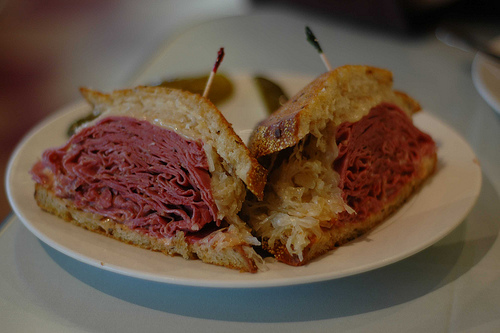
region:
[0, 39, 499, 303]
two halves of a sandwich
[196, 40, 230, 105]
toothpick sticking out of the sandwich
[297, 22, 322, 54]
top of the toothpick is green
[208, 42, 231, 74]
top of the toothpick is red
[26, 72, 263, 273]
meat between the bread slices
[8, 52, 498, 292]
round white plate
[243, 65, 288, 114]
pickle on the plate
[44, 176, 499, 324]
shadow from the plate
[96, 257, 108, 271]
speck on the edge of the plate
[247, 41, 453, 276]
A half sliced burgar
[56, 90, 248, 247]
A half sliced burgar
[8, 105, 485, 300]
A white plate of food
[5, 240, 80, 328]
A white plate surface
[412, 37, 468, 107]
A white plate surface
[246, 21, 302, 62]
A white plate surface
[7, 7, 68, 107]
A blurred photo background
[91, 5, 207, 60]
A blurred photo background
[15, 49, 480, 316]
a bunch of sandwhiches on a plate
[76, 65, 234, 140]
the bread of a sandwhich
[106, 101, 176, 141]
the cheese of a sandwhich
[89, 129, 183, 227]
the beef of a sandwhich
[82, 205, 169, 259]
the bottom bread of a sandwhich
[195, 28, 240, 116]
a tooth pick sticking out of a sandwhich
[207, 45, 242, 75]
a piece of plastic on a toothpick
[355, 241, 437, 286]
a white ceramic plate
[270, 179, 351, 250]
the saurkraut of a sandwhich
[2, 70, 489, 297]
A white round plate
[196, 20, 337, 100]
Two toothpicks on sandwiches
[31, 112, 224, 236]
A lot of ham in a sandwich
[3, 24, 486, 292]
Two sandwiches on a plate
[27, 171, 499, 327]
Plate's shadow on the table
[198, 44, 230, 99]
Red wrapper on a toothpick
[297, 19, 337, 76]
Green wrapper on a toothpick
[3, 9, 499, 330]
Plate is on a table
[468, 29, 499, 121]
The side of a plate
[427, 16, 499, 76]
A utensil on a plate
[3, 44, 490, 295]
SANDWICH SERVED ON PLATE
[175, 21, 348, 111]
TOOTH PICKS HOLDING SANDWICH TOGETHER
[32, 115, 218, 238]
SANDWICH HAS CORNED BEEF IN IT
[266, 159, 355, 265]
SANDWICH HAS SAUERKRAUT ON IT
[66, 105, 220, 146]
SANDWICH HAS SWISS CHEESE ON IT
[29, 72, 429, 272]
SANDWICH IS A REUBEN SANDWICH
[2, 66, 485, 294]
THE PLATE IS WHITE IN COLOR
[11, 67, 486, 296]
PLATE IS ROUND IN SHAPE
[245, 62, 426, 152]
SANDWICH IS MADE WITH RYE BREAD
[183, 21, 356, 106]
TOOTHPICKS ARE WOODEN